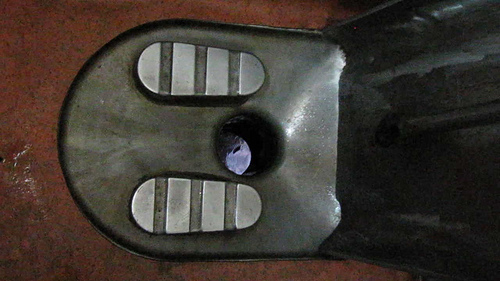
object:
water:
[220, 141, 253, 176]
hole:
[217, 105, 294, 184]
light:
[280, 86, 321, 142]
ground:
[0, 0, 499, 281]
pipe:
[397, 98, 496, 140]